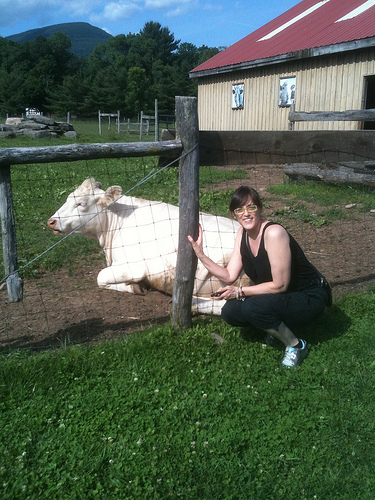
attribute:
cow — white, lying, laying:
[38, 164, 251, 303]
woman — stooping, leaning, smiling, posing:
[179, 173, 352, 373]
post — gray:
[166, 90, 204, 333]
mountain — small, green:
[1, 17, 124, 55]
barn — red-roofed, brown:
[153, 5, 374, 169]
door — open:
[352, 71, 374, 136]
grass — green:
[15, 356, 362, 496]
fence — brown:
[11, 94, 214, 351]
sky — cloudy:
[1, 4, 291, 53]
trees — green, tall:
[7, 19, 223, 116]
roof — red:
[182, 10, 374, 87]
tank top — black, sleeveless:
[232, 222, 324, 297]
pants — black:
[217, 278, 333, 332]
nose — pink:
[46, 216, 61, 232]